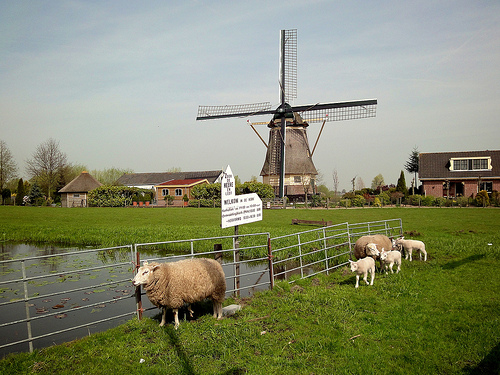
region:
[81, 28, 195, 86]
sky above the land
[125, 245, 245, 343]
animal on the ground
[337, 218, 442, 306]
baby animals and adult in grass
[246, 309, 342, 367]
grass next to the animal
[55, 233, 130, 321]
fence next to the animal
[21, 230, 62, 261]
reflection in the water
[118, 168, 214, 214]
building in the background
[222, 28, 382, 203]
object in the background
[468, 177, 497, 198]
window on the house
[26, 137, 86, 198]
branches on the tree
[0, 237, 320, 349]
A small pond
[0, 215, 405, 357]
some metal guard rails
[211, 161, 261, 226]
A white and black sign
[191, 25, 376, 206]
A large windmill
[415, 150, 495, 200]
A small stone house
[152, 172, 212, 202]
A small stone house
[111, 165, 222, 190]
a large white house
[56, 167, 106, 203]
A small shack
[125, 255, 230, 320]
a large adult white lamb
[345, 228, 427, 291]
A small group of sheep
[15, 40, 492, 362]
Pastoral scene with sheep and houses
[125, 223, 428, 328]
Two adult and three young sheep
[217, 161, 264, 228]
White sign with black lettering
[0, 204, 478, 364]
Sheep next to metal fencing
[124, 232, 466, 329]
Sheep strolling in green grass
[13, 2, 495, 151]
Grey partly cloudy skies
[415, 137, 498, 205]
Red brick house with attic windown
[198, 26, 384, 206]
Grey and white windmill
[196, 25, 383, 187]
Black windmill turbine and arms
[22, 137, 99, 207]
Bare tree next to house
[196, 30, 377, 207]
A windmill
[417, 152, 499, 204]
A house with a long window on the second floor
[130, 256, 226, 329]
A sheep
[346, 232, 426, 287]
A sheep with lambs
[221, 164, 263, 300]
A signpost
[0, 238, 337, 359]
A lake or pond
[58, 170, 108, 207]
A circular looking building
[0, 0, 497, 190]
Hazy looking sky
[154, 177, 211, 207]
A building with a brick red roof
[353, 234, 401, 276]
A sheep nuzzling a lamb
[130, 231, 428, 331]
Sheep standing on green grass.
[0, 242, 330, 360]
A pond with still water.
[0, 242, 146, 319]
Leaves floating on the surface of the water.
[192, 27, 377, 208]
A large windmill.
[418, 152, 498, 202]
A brick house with a brown roof.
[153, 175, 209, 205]
A red roof on a brick building.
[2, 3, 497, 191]
Light clouds in the sky.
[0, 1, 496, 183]
Blue sky behind clouds.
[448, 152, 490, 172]
A window with a white frame.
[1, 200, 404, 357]
A metal gate along the side of the pond.